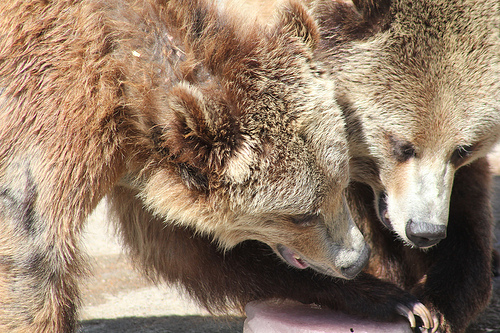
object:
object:
[240, 296, 414, 333]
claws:
[397, 302, 441, 333]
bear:
[297, 0, 499, 333]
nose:
[339, 240, 368, 279]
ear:
[301, 0, 392, 46]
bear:
[0, 0, 447, 333]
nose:
[401, 218, 448, 248]